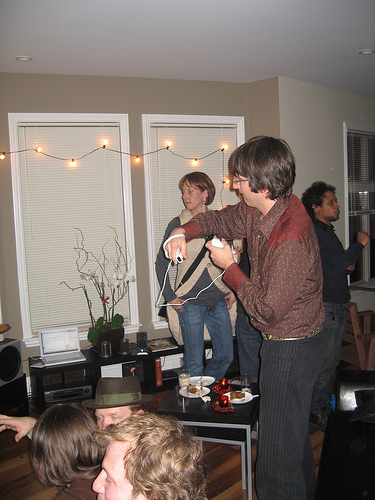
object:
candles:
[219, 394, 229, 408]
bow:
[58, 280, 82, 292]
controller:
[154, 233, 226, 308]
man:
[299, 178, 369, 435]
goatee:
[326, 208, 340, 223]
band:
[94, 392, 141, 406]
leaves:
[87, 328, 100, 346]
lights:
[165, 139, 173, 149]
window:
[8, 109, 144, 350]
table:
[156, 380, 259, 499]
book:
[144, 337, 178, 352]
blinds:
[16, 119, 131, 336]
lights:
[67, 159, 78, 168]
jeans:
[174, 300, 234, 384]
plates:
[177, 384, 211, 399]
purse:
[157, 232, 215, 320]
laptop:
[38, 326, 86, 366]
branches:
[71, 223, 85, 248]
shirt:
[313, 218, 365, 305]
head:
[93, 376, 144, 432]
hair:
[231, 135, 296, 201]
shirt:
[179, 191, 326, 339]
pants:
[254, 330, 327, 499]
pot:
[91, 321, 124, 353]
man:
[165, 134, 329, 499]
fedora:
[81, 376, 156, 409]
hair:
[300, 181, 336, 219]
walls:
[0, 77, 280, 377]